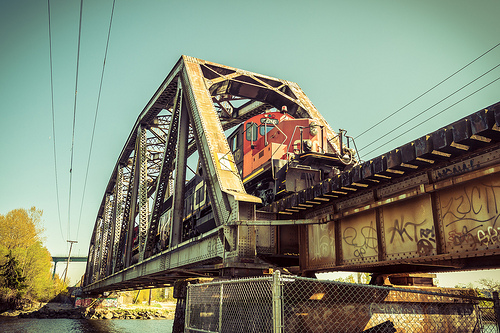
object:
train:
[102, 110, 351, 267]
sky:
[0, 1, 496, 285]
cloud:
[40, 184, 100, 289]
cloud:
[19, 120, 105, 212]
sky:
[197, 14, 448, 115]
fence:
[183, 263, 499, 330]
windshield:
[242, 121, 256, 139]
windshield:
[260, 123, 275, 135]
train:
[48, 102, 390, 263]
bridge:
[5, 83, 497, 325]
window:
[240, 121, 263, 141]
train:
[126, 100, 359, 221]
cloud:
[19, 41, 129, 158]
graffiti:
[337, 178, 499, 258]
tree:
[0, 203, 68, 319]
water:
[2, 320, 165, 331]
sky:
[205, 0, 472, 95]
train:
[88, 105, 356, 289]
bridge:
[119, 173, 489, 266]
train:
[71, 103, 363, 292]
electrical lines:
[47, 0, 119, 262]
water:
[9, 317, 166, 332]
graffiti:
[386, 212, 434, 255]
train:
[110, 104, 363, 257]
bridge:
[75, 55, 356, 289]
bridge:
[31, 66, 498, 286]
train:
[92, 102, 359, 258]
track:
[259, 102, 492, 211]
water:
[0, 314, 173, 332]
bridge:
[74, 53, 499, 295]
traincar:
[231, 115, 353, 196]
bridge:
[278, 184, 492, 281]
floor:
[279, 150, 327, 197]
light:
[279, 104, 290, 114]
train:
[123, 102, 361, 251]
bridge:
[52, 63, 497, 332]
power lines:
[32, 1, 122, 286]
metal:
[292, 177, 499, 270]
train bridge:
[64, 55, 491, 329]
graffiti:
[370, 190, 495, 254]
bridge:
[69, 52, 479, 331]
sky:
[3, 0, 420, 283]